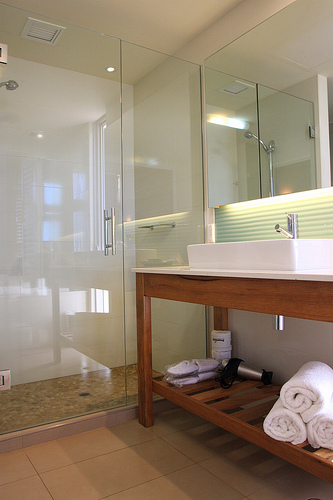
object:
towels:
[279, 360, 332, 425]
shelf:
[152, 358, 332, 484]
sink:
[186, 236, 332, 271]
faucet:
[274, 212, 299, 240]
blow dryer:
[214, 357, 274, 390]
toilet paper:
[211, 329, 232, 364]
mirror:
[204, 0, 333, 208]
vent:
[21, 17, 66, 45]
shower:
[13, 70, 120, 354]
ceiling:
[146, 9, 201, 29]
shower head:
[243, 130, 275, 155]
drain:
[78, 392, 97, 403]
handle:
[104, 205, 117, 255]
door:
[0, 2, 128, 435]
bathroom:
[0, 2, 321, 437]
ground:
[189, 435, 226, 499]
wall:
[278, 333, 317, 359]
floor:
[42, 447, 210, 495]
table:
[130, 264, 332, 483]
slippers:
[167, 356, 220, 378]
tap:
[0, 79, 20, 91]